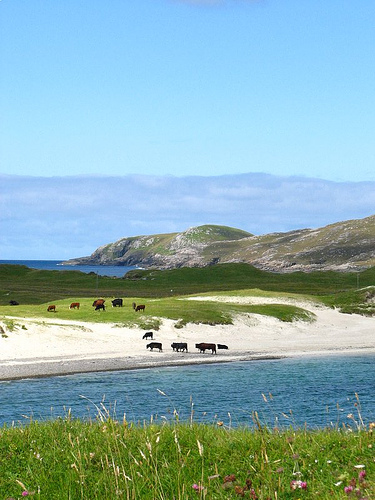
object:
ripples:
[184, 386, 314, 406]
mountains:
[60, 212, 373, 277]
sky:
[0, 0, 375, 261]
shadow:
[174, 350, 226, 355]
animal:
[176, 342, 188, 352]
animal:
[217, 343, 229, 349]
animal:
[170, 342, 182, 352]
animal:
[146, 342, 163, 352]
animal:
[142, 331, 154, 340]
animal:
[132, 301, 136, 310]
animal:
[111, 298, 123, 307]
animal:
[92, 298, 104, 308]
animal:
[69, 302, 81, 310]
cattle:
[9, 299, 19, 305]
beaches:
[0, 297, 370, 378]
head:
[68, 306, 71, 310]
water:
[0, 355, 372, 427]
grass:
[0, 411, 372, 498]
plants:
[2, 389, 371, 498]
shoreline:
[2, 339, 374, 383]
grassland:
[0, 257, 375, 335]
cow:
[135, 304, 145, 312]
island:
[0, 262, 372, 381]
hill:
[144, 222, 253, 267]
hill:
[200, 224, 311, 266]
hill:
[272, 211, 373, 270]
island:
[56, 220, 373, 268]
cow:
[47, 304, 56, 313]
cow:
[94, 303, 107, 311]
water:
[3, 257, 146, 278]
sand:
[0, 291, 374, 386]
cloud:
[0, 170, 373, 262]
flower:
[223, 473, 235, 484]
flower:
[291, 479, 308, 491]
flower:
[191, 482, 204, 492]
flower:
[344, 485, 353, 495]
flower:
[359, 470, 367, 480]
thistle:
[193, 464, 302, 493]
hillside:
[1, 388, 373, 497]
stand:
[0, 286, 373, 378]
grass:
[0, 263, 373, 335]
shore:
[0, 296, 373, 379]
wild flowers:
[0, 411, 375, 497]